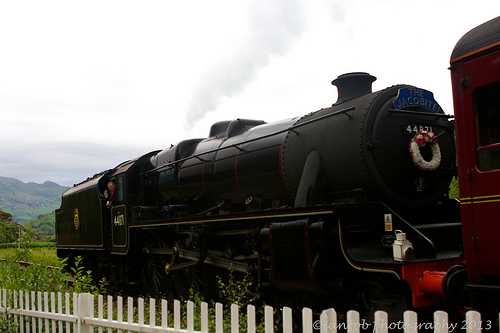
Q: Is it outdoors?
A: Yes, it is outdoors.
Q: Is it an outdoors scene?
A: Yes, it is outdoors.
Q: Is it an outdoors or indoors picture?
A: It is outdoors.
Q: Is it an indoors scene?
A: No, it is outdoors.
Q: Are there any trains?
A: Yes, there is a train.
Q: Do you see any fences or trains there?
A: Yes, there is a train.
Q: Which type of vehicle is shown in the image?
A: The vehicle is a train.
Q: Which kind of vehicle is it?
A: The vehicle is a train.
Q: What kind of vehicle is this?
A: This is a train.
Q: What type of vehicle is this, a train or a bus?
A: This is a train.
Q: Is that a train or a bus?
A: That is a train.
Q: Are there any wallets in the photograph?
A: No, there are no wallets.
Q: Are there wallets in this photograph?
A: No, there are no wallets.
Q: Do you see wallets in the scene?
A: No, there are no wallets.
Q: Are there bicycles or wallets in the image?
A: No, there are no wallets or bicycles.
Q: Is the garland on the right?
A: Yes, the garland is on the right of the image.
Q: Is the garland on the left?
A: No, the garland is on the right of the image.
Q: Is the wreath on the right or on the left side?
A: The wreath is on the right of the image.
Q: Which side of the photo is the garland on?
A: The garland is on the right of the image.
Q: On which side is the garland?
A: The garland is on the right of the image.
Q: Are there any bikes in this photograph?
A: No, there are no bikes.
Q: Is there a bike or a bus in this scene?
A: No, there are no bikes or buses.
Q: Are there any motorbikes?
A: No, there are no motorbikes.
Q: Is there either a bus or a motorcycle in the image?
A: No, there are no motorcycles or buses.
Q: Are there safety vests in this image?
A: No, there are no safety vests.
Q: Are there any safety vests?
A: No, there are no safety vests.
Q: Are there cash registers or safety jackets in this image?
A: No, there are no safety jackets or cash registers.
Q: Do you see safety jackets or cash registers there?
A: No, there are no safety jackets or cash registers.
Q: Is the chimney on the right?
A: Yes, the chimney is on the right of the image.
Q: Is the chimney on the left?
A: No, the chimney is on the right of the image.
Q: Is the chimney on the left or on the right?
A: The chimney is on the right of the image.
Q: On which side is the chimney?
A: The chimney is on the right of the image.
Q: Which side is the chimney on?
A: The chimney is on the right of the image.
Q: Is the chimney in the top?
A: Yes, the chimney is in the top of the image.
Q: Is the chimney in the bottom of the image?
A: No, the chimney is in the top of the image.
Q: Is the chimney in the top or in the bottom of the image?
A: The chimney is in the top of the image.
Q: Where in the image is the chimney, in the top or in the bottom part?
A: The chimney is in the top of the image.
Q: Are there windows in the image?
A: Yes, there is a window.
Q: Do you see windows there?
A: Yes, there is a window.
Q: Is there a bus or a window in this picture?
A: Yes, there is a window.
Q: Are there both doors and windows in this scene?
A: No, there is a window but no doors.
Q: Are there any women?
A: No, there are no women.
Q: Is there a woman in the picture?
A: No, there are no women.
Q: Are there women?
A: No, there are no women.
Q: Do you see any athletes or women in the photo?
A: No, there are no women or athletes.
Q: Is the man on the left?
A: Yes, the man is on the left of the image.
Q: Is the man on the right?
A: No, the man is on the left of the image.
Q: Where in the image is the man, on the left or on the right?
A: The man is on the left of the image.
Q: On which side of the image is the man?
A: The man is on the left of the image.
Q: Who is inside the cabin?
A: The man is inside the cabin.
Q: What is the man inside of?
A: The man is inside the cabin.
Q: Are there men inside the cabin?
A: Yes, there is a man inside the cabin.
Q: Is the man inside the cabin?
A: Yes, the man is inside the cabin.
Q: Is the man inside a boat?
A: No, the man is inside the cabin.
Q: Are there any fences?
A: Yes, there is a fence.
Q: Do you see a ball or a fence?
A: Yes, there is a fence.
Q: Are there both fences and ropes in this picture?
A: No, there is a fence but no ropes.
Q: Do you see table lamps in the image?
A: No, there are no table lamps.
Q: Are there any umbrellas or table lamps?
A: No, there are no table lamps or umbrellas.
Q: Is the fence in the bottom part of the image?
A: Yes, the fence is in the bottom of the image.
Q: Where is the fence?
A: The fence is on the grass.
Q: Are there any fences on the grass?
A: Yes, there is a fence on the grass.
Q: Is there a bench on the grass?
A: No, there is a fence on the grass.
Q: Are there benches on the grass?
A: No, there is a fence on the grass.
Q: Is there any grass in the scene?
A: Yes, there is grass.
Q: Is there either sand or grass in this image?
A: Yes, there is grass.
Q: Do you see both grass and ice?
A: No, there is grass but no ice.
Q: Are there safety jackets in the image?
A: No, there are no safety jackets.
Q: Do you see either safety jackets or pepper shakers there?
A: No, there are no safety jackets or pepper shakers.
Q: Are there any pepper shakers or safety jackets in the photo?
A: No, there are no safety jackets or pepper shakers.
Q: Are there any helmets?
A: No, there are no helmets.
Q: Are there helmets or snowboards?
A: No, there are no helmets or snowboards.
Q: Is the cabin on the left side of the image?
A: Yes, the cabin is on the left of the image.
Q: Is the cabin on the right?
A: No, the cabin is on the left of the image.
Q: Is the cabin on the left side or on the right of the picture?
A: The cabin is on the left of the image.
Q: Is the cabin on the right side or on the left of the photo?
A: The cabin is on the left of the image.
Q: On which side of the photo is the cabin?
A: The cabin is on the left of the image.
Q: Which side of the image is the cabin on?
A: The cabin is on the left of the image.